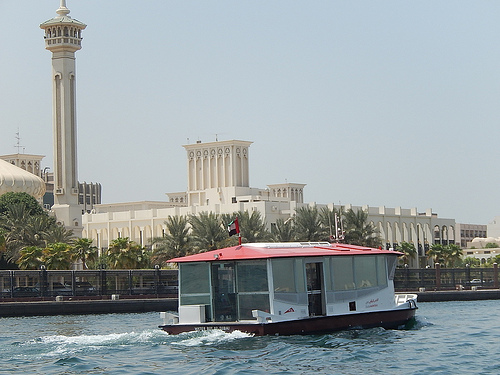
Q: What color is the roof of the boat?
A: Red.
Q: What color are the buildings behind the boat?
A: Cream.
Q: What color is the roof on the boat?
A: Red.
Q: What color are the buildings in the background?
A: White.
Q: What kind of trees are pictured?
A: Palm.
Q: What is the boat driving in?
A: Water.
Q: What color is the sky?
A: Blue.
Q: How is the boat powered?
A: Engine.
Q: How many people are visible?
A: None.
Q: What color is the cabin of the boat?
A: White.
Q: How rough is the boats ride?
A: Smooth.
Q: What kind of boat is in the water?
A: House boat.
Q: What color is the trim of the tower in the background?
A: Gold.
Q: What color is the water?
A: Blue.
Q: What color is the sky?
A: Blue.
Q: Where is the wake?
A: Behind the boat.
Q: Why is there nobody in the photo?
A: They are driving the boat.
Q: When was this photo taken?
A: In the afternoon.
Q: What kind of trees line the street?
A: Palm trees.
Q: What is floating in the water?
A: A houseboat.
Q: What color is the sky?
A: Blue.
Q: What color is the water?
A: Blue.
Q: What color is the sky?
A: Blue.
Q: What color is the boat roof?
A: Red.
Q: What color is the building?
A: White.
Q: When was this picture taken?
A: Daytime.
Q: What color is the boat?
A: White.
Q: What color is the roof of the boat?
A: Red.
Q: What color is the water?
A: Blue.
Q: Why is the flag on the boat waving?
A: It's windy.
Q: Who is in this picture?
A: No one.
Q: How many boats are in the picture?
A: One.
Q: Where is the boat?
A: In the water.